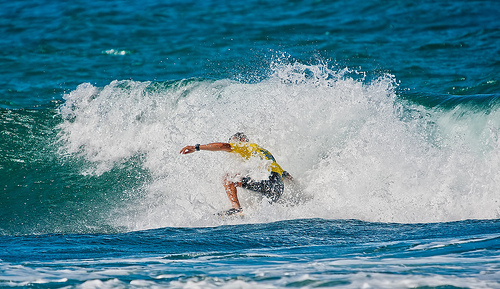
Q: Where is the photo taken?
A: Ocean.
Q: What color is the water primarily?
A: Blue.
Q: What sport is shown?
A: Surfing.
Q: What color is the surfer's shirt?
A: Yellow.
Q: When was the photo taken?
A: Daytime.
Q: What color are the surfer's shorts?
A: Black.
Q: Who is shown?
A: Surfer.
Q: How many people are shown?
A: One.